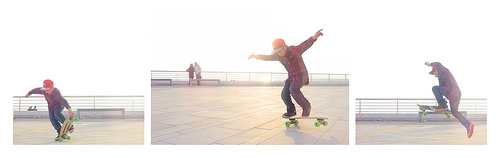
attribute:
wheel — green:
[63, 118, 73, 124]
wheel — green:
[55, 136, 65, 151]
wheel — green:
[307, 109, 334, 134]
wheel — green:
[311, 117, 330, 127]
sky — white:
[17, 6, 144, 95]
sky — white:
[152, 0, 348, 68]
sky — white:
[354, 15, 489, 97]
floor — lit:
[153, 81, 347, 146]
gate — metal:
[153, 68, 351, 89]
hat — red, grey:
[271, 42, 283, 51]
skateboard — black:
[56, 110, 76, 141]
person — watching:
[186, 62, 195, 86]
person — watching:
[193, 61, 202, 84]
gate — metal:
[12, 92, 144, 112]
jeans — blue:
[279, 78, 313, 113]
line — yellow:
[13, 114, 53, 143]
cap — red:
[271, 36, 287, 51]